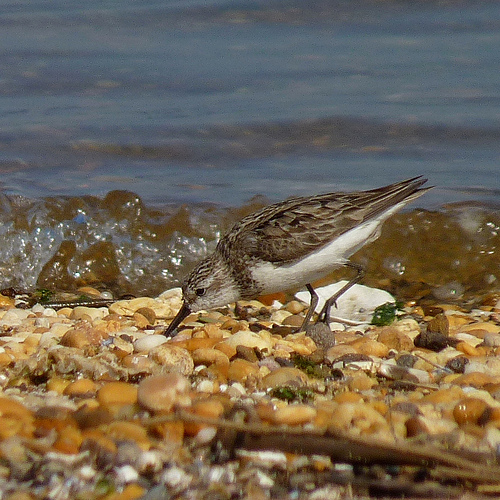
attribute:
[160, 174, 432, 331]
bird — gray, white, searching, scavenging, alone, looking, finding, brown, drinking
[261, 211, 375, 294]
underbelly — white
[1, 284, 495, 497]
pebbles — brown, orange, white, yellow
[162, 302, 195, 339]
beak — long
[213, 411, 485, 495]
twigs — brown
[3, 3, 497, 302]
water — calm, brown, gray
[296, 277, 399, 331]
seashell — white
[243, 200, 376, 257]
wing — brown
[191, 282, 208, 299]
eye — small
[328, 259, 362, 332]
foot — up